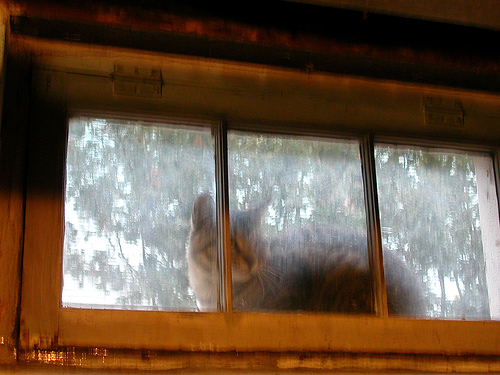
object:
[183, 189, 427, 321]
cat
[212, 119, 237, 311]
dividers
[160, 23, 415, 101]
boarder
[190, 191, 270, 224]
ears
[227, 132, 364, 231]
tree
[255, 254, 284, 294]
whiskers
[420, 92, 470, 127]
hinge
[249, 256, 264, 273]
nose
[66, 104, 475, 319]
windows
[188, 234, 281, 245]
eyes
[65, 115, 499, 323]
trees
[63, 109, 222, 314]
window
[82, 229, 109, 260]
sky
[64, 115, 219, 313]
pane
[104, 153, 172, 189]
leaves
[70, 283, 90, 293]
light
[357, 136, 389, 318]
rod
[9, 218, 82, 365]
wall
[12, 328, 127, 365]
goop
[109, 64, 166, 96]
rivet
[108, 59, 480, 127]
rivets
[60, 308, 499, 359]
frame